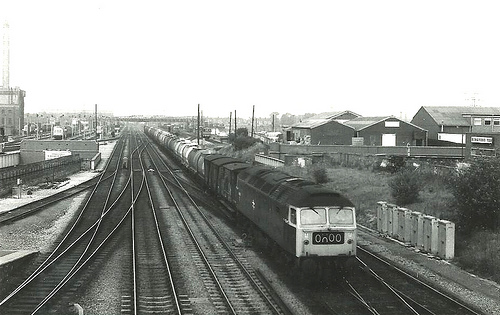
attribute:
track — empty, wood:
[128, 147, 163, 308]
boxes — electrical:
[372, 198, 464, 254]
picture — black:
[10, 5, 490, 314]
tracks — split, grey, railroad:
[41, 130, 408, 308]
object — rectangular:
[435, 220, 454, 265]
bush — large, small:
[447, 154, 499, 205]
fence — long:
[314, 141, 457, 155]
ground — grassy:
[291, 138, 499, 256]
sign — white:
[468, 138, 494, 146]